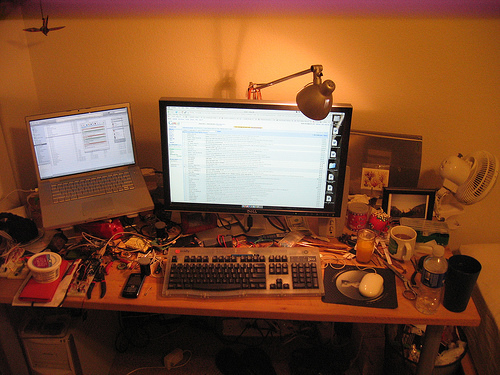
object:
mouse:
[358, 271, 385, 296]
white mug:
[387, 224, 418, 260]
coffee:
[392, 233, 412, 241]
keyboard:
[161, 247, 326, 300]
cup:
[441, 253, 481, 313]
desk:
[0, 190, 482, 373]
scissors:
[382, 261, 420, 300]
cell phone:
[122, 272, 145, 299]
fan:
[434, 149, 499, 229]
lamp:
[246, 64, 336, 121]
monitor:
[158, 96, 352, 218]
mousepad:
[320, 263, 398, 310]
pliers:
[86, 264, 108, 299]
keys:
[274, 278, 282, 283]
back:
[440, 151, 497, 203]